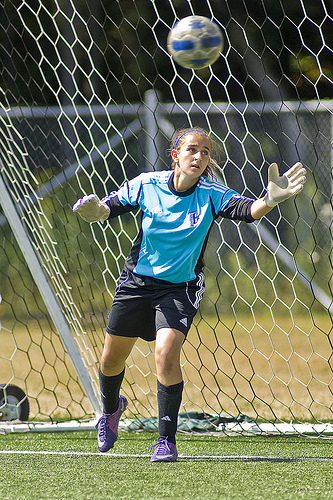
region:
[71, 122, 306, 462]
Woman wearing white gloves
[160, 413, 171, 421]
White Adidas logo on black sock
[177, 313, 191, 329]
White Adidas logo on black shorts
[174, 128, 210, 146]
Blue headband on head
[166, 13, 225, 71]
Ball is white and blue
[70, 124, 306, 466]
Woman reaching out to block ball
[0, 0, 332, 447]
Soccer net behind woman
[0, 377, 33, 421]
Round black wheel by net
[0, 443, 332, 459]
White line on grass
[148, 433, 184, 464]
Shoe is all purple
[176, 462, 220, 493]
the grass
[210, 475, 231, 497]
the grass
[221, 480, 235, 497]
the grass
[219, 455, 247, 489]
the grass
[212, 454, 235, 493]
the grass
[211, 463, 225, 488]
the grass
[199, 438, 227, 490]
the grass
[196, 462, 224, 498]
the grass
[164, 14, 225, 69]
blue and white soccer ball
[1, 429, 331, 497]
green artificial turf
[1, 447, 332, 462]
white line on the soccer field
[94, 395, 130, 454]
purple and pink soccer cleat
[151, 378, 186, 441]
black socks with shinguard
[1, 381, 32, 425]
black and silver tire next to the goal net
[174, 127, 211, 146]
blue headband on the girl's head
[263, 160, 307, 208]
white goalie glove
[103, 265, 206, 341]
girl wearing black soccer shorts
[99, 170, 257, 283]
blue and black soccer uniform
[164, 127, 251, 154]
girl is wearing blue headband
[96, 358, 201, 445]
girl wearing black socks and shinguards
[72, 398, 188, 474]
girl's cleats are purple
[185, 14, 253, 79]
soccer ball is blue and white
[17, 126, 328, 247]
girl wearing goalie gloves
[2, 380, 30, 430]
wheel behind soccer net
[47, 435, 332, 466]
girl standing on goal line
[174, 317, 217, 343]
addias logo on shorts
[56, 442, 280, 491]
soccer field is grass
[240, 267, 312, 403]
netting of soccer net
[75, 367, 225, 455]
a pair of black socks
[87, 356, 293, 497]
a pair of black socks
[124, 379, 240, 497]
a pair of black socks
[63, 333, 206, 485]
a pair of black socks